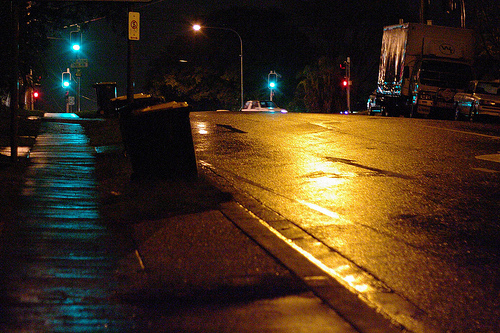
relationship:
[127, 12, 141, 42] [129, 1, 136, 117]
sign on post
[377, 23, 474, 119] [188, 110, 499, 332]
truck on street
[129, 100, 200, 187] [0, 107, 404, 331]
garbage on side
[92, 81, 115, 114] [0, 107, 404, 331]
garbage on side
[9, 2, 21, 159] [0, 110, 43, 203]
pole in yard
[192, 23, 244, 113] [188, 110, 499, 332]
streetlight on street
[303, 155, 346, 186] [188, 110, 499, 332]
reflection on street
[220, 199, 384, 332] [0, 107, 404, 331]
curb on side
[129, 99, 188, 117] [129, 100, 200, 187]
lid of garbage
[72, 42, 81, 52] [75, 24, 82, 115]
light on post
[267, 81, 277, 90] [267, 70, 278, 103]
light on post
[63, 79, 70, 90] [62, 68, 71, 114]
light on post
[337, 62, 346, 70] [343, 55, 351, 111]
signal on post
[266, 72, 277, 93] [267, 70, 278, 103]
signal on post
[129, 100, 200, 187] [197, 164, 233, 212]
garbage on curb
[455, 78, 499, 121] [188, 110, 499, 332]
car on street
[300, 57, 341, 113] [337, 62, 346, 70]
tree behind signal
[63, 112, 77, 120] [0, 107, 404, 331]
reflection on side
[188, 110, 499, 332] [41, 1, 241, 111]
street at night